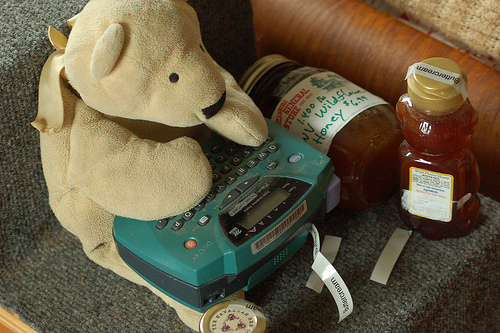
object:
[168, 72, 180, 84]
right eye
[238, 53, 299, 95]
lid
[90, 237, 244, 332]
leg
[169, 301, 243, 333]
foot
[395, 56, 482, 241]
honey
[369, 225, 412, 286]
tag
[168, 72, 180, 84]
eye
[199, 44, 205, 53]
eye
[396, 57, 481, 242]
bottle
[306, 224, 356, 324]
sticker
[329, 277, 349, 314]
writing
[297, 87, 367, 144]
writing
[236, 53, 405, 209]
bottle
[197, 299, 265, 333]
bottle top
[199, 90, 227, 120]
nose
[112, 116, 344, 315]
labeler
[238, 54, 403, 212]
honey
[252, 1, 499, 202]
side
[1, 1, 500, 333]
chair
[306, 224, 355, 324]
paper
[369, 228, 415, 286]
paper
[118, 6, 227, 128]
face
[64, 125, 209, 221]
arm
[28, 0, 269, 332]
bear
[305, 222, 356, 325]
labels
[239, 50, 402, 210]
honey jars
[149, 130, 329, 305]
label maker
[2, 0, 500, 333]
stairs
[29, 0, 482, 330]
collectables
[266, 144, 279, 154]
key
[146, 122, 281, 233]
keyboard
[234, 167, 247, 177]
key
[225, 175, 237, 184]
key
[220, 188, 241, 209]
key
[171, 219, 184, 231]
key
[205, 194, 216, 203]
key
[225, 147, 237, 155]
key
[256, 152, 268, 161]
key